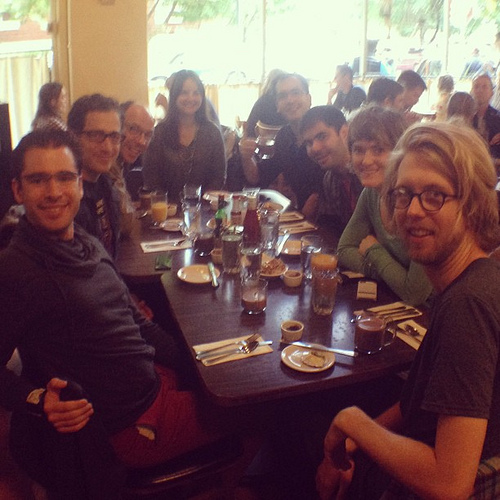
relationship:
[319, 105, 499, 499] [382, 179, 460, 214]
man in glasses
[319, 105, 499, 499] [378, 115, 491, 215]
man with hair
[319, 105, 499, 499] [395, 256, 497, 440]
man in shirt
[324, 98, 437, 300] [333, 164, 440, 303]
woman in shirt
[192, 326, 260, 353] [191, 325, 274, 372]
fork on napkin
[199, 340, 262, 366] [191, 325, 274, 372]
silverware on napkin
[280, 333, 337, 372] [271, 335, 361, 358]
plate with knife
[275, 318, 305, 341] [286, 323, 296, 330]
cup of coffee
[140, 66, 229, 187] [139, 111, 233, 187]
woman in shirt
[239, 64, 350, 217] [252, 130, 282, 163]
man holding drink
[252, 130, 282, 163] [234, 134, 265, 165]
drink in hand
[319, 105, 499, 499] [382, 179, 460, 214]
man with glasses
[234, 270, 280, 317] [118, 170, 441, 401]
mug on table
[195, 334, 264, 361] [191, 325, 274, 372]
silverware on napkin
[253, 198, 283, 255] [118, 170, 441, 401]
glass on table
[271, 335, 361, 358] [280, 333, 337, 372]
knife on plate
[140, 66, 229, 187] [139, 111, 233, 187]
woman wearing shirt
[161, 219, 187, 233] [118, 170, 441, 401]
bowl on table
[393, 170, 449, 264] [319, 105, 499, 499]
face of man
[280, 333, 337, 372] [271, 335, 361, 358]
plate and knife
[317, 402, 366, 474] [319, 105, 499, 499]
hand of man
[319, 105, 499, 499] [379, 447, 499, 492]
man on chair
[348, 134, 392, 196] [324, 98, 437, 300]
face of woman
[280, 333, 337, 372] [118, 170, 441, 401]
plate on table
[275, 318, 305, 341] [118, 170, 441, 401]
cup on table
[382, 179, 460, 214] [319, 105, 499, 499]
glasses on man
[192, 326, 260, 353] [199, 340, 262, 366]
fork next to silverware